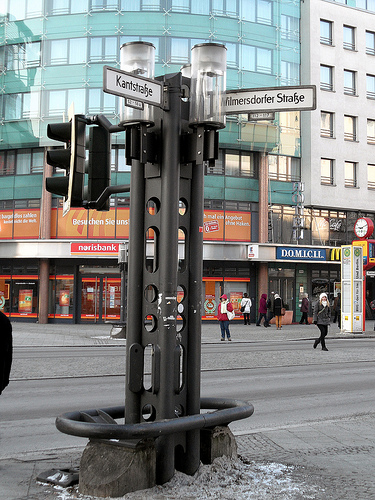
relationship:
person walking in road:
[299, 291, 310, 323] [0, 320, 375, 499]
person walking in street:
[269, 292, 286, 333] [0, 333, 373, 458]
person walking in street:
[313, 292, 330, 351] [0, 333, 373, 458]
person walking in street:
[298, 290, 310, 323] [214, 269, 364, 414]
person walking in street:
[255, 292, 271, 326] [214, 269, 364, 414]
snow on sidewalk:
[212, 463, 243, 480] [303, 421, 345, 468]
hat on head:
[318, 292, 330, 305] [316, 289, 328, 302]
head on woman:
[316, 289, 328, 302] [310, 290, 333, 351]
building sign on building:
[79, 243, 117, 253] [1, 1, 374, 321]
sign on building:
[218, 86, 315, 114] [1, 1, 374, 321]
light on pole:
[39, 117, 77, 194] [119, 119, 147, 427]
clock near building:
[354, 217, 372, 237] [300, 0, 373, 323]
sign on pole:
[103, 65, 164, 107] [154, 70, 183, 487]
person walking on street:
[313, 292, 330, 351] [150, 307, 271, 432]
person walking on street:
[313, 292, 330, 351] [3, 323, 373, 497]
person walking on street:
[213, 290, 238, 343] [3, 323, 373, 497]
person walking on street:
[269, 291, 285, 329] [3, 323, 373, 497]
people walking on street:
[240, 291, 252, 326] [3, 323, 373, 497]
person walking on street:
[0, 286, 16, 407] [3, 323, 373, 497]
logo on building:
[329, 246, 341, 259] [292, 2, 373, 317]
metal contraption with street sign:
[39, 37, 281, 456] [219, 77, 327, 131]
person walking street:
[313, 292, 330, 351] [289, 340, 361, 387]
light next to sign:
[186, 37, 228, 124] [218, 86, 315, 114]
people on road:
[239, 286, 292, 331] [0, 320, 375, 499]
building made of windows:
[1, 1, 374, 321] [1, 1, 300, 205]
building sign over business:
[281, 248, 325, 259] [271, 243, 371, 323]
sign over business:
[218, 86, 315, 108] [2, 206, 254, 324]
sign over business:
[103, 65, 164, 101] [2, 206, 254, 324]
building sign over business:
[79, 243, 117, 253] [2, 206, 254, 324]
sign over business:
[339, 244, 363, 330] [271, 243, 371, 323]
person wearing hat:
[216, 291, 234, 341] [219, 294, 227, 300]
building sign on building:
[281, 248, 325, 259] [261, 185, 358, 319]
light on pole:
[45, 114, 76, 217] [118, 124, 143, 433]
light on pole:
[186, 37, 228, 124] [125, 137, 202, 483]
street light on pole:
[119, 41, 154, 78] [125, 137, 202, 483]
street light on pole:
[117, 96, 153, 126] [125, 137, 202, 483]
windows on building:
[226, 153, 253, 177] [1, 1, 374, 321]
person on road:
[313, 292, 330, 351] [0, 320, 374, 457]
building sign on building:
[281, 248, 325, 259] [1, 1, 374, 321]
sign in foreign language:
[218, 86, 315, 114] [111, 72, 312, 110]